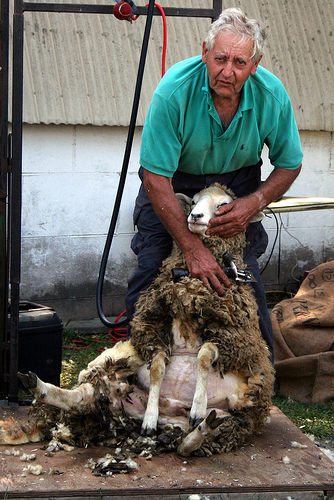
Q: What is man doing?
A: Shearing sheep.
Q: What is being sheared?
A: Sheep.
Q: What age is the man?
A: Old.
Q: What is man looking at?
A: Camera.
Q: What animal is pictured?
A: Sheep.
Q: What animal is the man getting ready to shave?
A: Sheep.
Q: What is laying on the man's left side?
A: Burlap bag.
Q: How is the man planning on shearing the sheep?
A: Razor.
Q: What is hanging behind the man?
A: Hose.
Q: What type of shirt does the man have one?
A: Polo.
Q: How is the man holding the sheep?
A: From behind.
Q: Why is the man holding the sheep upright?
A: To shave him.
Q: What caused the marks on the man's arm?
A: A watch.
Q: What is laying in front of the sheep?
A: Fur.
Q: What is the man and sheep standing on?
A: Platform.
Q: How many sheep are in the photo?
A: One.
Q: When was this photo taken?
A: Daytime.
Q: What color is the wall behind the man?
A: White.